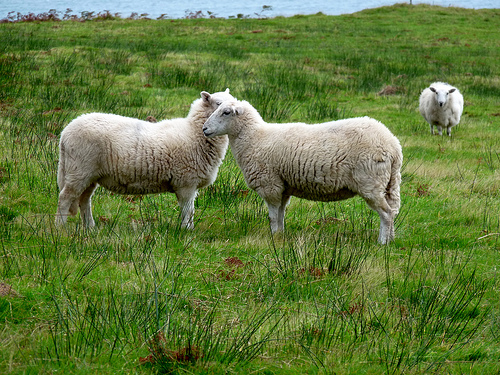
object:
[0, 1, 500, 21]
ocean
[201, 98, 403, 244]
sheep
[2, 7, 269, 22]
bushes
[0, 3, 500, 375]
field